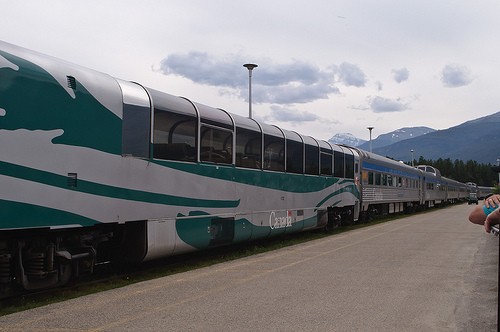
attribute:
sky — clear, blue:
[4, 1, 498, 144]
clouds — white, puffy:
[160, 49, 473, 130]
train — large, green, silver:
[0, 40, 491, 293]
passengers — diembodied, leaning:
[459, 187, 496, 238]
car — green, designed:
[1, 42, 363, 296]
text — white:
[264, 206, 297, 232]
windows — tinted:
[139, 77, 354, 179]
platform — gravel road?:
[4, 194, 500, 329]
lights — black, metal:
[243, 58, 419, 156]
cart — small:
[466, 190, 480, 206]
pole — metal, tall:
[243, 62, 258, 120]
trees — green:
[408, 156, 496, 189]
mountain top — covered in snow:
[332, 129, 368, 147]